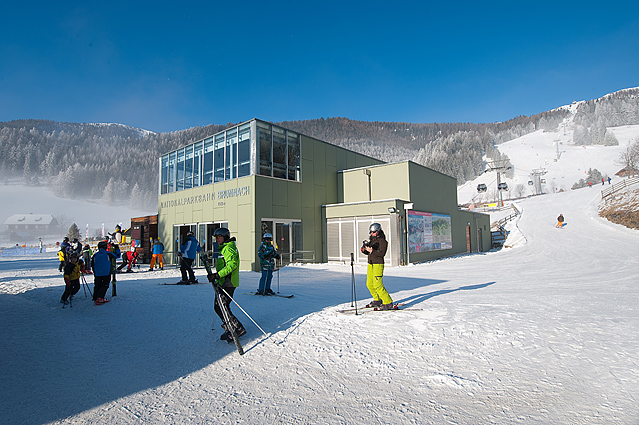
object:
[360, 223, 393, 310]
person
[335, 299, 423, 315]
ski gear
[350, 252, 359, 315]
ski poles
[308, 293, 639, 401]
snow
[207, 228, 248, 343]
person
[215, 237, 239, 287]
coat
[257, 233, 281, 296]
person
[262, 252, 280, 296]
ski poles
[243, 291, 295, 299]
skis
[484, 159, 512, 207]
ski lift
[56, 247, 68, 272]
person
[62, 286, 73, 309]
ski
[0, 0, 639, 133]
skies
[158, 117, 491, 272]
building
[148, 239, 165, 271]
person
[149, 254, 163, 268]
pants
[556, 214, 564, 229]
person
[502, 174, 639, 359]
hill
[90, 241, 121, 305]
skiiers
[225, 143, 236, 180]
glass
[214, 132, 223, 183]
glass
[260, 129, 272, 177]
glass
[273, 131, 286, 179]
glass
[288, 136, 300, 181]
glass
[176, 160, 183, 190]
glass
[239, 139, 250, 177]
glass